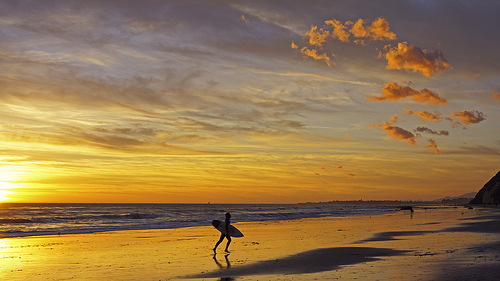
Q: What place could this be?
A: It is a beach.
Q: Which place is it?
A: It is a beach.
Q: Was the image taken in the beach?
A: Yes, it was taken in the beach.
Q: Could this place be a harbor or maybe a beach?
A: It is a beach.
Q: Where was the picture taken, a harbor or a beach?
A: It was taken at a beach.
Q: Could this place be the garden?
A: No, it is the beach.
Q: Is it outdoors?
A: Yes, it is outdoors.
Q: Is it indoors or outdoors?
A: It is outdoors.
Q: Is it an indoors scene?
A: No, it is outdoors.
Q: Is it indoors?
A: No, it is outdoors.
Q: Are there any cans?
A: No, there are no cans.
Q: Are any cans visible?
A: No, there are no cans.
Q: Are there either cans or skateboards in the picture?
A: No, there are no cans or skateboards.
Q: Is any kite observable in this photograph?
A: No, there are no kites.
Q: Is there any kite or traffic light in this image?
A: No, there are no kites or traffic lights.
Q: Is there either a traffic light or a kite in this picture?
A: No, there are no kites or traffic lights.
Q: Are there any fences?
A: No, there are no fences.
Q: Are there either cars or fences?
A: No, there are no fences or cars.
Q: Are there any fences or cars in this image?
A: No, there are no fences or cars.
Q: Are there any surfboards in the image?
A: Yes, there is a surfboard.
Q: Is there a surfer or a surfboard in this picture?
A: Yes, there is a surfboard.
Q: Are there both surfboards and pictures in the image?
A: No, there is a surfboard but no pictures.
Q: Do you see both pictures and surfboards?
A: No, there is a surfboard but no pictures.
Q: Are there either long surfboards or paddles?
A: Yes, there is a long surfboard.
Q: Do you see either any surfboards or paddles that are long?
A: Yes, the surfboard is long.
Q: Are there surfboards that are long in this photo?
A: Yes, there is a long surfboard.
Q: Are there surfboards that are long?
A: Yes, there is a surfboard that is long.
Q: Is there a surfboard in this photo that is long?
A: Yes, there is a surfboard that is long.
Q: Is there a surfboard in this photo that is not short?
A: Yes, there is a long surfboard.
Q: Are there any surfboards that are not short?
A: Yes, there is a long surfboard.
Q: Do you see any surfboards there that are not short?
A: Yes, there is a long surfboard.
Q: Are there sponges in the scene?
A: No, there are no sponges.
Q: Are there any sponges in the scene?
A: No, there are no sponges.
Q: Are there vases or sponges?
A: No, there are no sponges or vases.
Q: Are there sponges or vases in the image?
A: No, there are no sponges or vases.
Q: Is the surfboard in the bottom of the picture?
A: Yes, the surfboard is in the bottom of the image.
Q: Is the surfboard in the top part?
A: No, the surfboard is in the bottom of the image.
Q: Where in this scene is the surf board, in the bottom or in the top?
A: The surf board is in the bottom of the image.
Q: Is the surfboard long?
A: Yes, the surfboard is long.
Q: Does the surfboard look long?
A: Yes, the surfboard is long.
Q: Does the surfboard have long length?
A: Yes, the surfboard is long.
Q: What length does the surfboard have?
A: The surfboard has long length.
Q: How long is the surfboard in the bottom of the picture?
A: The surfboard is long.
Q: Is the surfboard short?
A: No, the surfboard is long.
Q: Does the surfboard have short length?
A: No, the surfboard is long.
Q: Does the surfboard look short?
A: No, the surfboard is long.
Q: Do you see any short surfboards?
A: No, there is a surfboard but it is long.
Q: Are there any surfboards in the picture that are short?
A: No, there is a surfboard but it is long.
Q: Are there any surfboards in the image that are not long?
A: No, there is a surfboard but it is long.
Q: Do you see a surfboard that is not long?
A: No, there is a surfboard but it is long.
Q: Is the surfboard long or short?
A: The surfboard is long.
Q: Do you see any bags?
A: No, there are no bags.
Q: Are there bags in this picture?
A: No, there are no bags.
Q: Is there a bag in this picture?
A: No, there are no bags.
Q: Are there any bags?
A: No, there are no bags.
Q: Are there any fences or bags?
A: No, there are no bags or fences.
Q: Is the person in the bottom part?
A: Yes, the person is in the bottom of the image.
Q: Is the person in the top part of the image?
A: No, the person is in the bottom of the image.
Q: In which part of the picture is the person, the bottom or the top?
A: The person is in the bottom of the image.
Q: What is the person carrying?
A: The person is carrying a surfboard.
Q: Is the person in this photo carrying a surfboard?
A: Yes, the person is carrying a surfboard.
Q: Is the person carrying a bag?
A: No, the person is carrying a surfboard.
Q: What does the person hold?
A: The person holds the surfboard.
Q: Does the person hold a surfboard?
A: Yes, the person holds a surfboard.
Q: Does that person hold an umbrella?
A: No, the person holds a surfboard.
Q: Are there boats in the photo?
A: No, there are no boats.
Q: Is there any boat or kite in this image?
A: No, there are no boats or kites.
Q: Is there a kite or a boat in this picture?
A: No, there are no boats or kites.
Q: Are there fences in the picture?
A: No, there are no fences.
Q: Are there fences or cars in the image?
A: No, there are no fences or cars.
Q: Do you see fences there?
A: No, there are no fences.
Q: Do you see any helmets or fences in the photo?
A: No, there are no fences or helmets.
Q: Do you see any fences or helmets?
A: No, there are no fences or helmets.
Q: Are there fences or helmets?
A: No, there are no fences or helmets.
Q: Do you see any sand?
A: Yes, there is sand.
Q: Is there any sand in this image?
A: Yes, there is sand.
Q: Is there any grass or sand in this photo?
A: Yes, there is sand.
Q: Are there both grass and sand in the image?
A: No, there is sand but no grass.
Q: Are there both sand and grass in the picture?
A: No, there is sand but no grass.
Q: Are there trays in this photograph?
A: No, there are no trays.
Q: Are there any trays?
A: No, there are no trays.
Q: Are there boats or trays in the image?
A: No, there are no trays or boats.